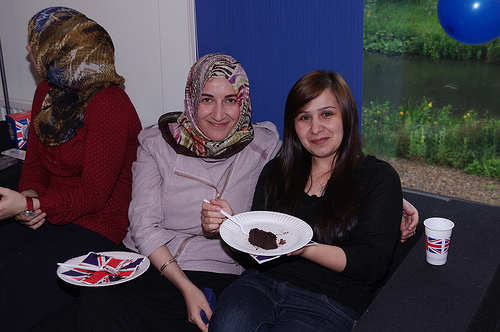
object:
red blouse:
[16, 77, 140, 245]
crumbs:
[62, 251, 143, 285]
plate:
[57, 251, 150, 286]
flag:
[60, 251, 146, 281]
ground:
[393, 130, 435, 171]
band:
[160, 258, 177, 271]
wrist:
[175, 278, 195, 292]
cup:
[424, 217, 454, 265]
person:
[0, 12, 136, 332]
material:
[157, 51, 256, 161]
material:
[25, 6, 124, 147]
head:
[284, 70, 353, 158]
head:
[183, 52, 251, 140]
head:
[27, 4, 114, 93]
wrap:
[161, 49, 256, 159]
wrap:
[20, 4, 123, 147]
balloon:
[430, 0, 495, 47]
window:
[198, 7, 499, 206]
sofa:
[403, 189, 497, 329]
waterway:
[364, 43, 499, 123]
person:
[199, 71, 403, 330]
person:
[135, 44, 275, 329]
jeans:
[208, 270, 371, 331]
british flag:
[426, 235, 442, 255]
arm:
[126, 142, 197, 293]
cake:
[247, 228, 277, 247]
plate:
[219, 211, 313, 255]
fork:
[202, 198, 251, 236]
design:
[426, 235, 451, 255]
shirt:
[248, 149, 401, 307]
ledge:
[356, 198, 497, 331]